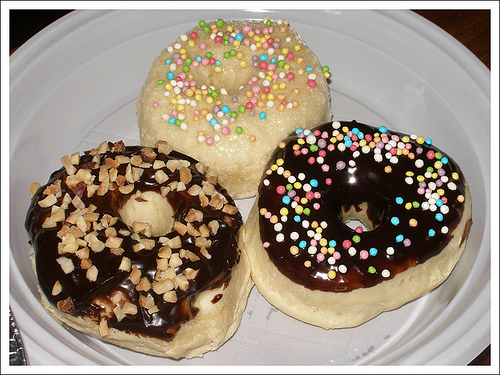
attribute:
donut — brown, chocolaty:
[22, 143, 250, 362]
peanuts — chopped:
[26, 138, 237, 340]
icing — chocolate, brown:
[24, 140, 246, 340]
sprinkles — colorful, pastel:
[177, 30, 301, 132]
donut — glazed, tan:
[137, 16, 336, 200]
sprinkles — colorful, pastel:
[283, 140, 423, 248]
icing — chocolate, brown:
[265, 123, 465, 293]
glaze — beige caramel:
[158, 35, 287, 141]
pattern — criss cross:
[230, 302, 365, 364]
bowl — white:
[11, 12, 497, 368]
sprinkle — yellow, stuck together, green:
[322, 62, 333, 81]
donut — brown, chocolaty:
[245, 118, 475, 333]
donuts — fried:
[30, 19, 473, 358]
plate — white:
[9, 10, 492, 367]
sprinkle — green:
[234, 121, 245, 137]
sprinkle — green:
[351, 231, 362, 244]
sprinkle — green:
[181, 54, 195, 67]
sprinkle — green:
[282, 179, 295, 193]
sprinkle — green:
[215, 17, 226, 28]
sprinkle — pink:
[241, 23, 253, 33]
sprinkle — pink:
[260, 24, 273, 35]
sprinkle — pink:
[272, 182, 288, 197]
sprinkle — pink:
[303, 189, 316, 202]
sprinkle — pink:
[340, 236, 354, 252]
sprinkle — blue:
[165, 114, 178, 126]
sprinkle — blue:
[256, 110, 270, 121]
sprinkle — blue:
[166, 70, 180, 81]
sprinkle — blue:
[434, 211, 445, 225]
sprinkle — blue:
[427, 227, 437, 238]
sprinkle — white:
[177, 30, 189, 44]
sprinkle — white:
[211, 131, 222, 146]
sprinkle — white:
[272, 221, 285, 233]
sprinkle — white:
[445, 178, 458, 194]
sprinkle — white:
[288, 230, 300, 241]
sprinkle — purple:
[271, 40, 281, 50]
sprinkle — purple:
[250, 53, 259, 63]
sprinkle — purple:
[212, 104, 223, 114]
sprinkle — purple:
[374, 140, 385, 150]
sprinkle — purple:
[401, 235, 412, 249]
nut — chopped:
[51, 254, 76, 279]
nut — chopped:
[178, 163, 194, 186]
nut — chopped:
[151, 167, 170, 184]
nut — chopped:
[68, 194, 87, 211]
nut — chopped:
[114, 151, 131, 165]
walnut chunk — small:
[165, 251, 182, 269]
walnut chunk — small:
[171, 218, 187, 235]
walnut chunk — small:
[196, 190, 209, 210]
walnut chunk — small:
[208, 193, 225, 212]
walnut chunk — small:
[199, 245, 209, 259]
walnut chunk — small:
[174, 270, 191, 292]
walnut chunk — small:
[208, 218, 221, 237]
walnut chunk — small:
[184, 220, 200, 235]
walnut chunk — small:
[193, 235, 213, 248]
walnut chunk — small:
[182, 266, 201, 283]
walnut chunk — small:
[160, 292, 182, 304]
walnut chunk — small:
[180, 248, 199, 265]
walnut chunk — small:
[183, 206, 206, 222]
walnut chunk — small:
[186, 183, 202, 198]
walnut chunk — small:
[120, 303, 137, 317]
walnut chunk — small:
[145, 304, 161, 317]